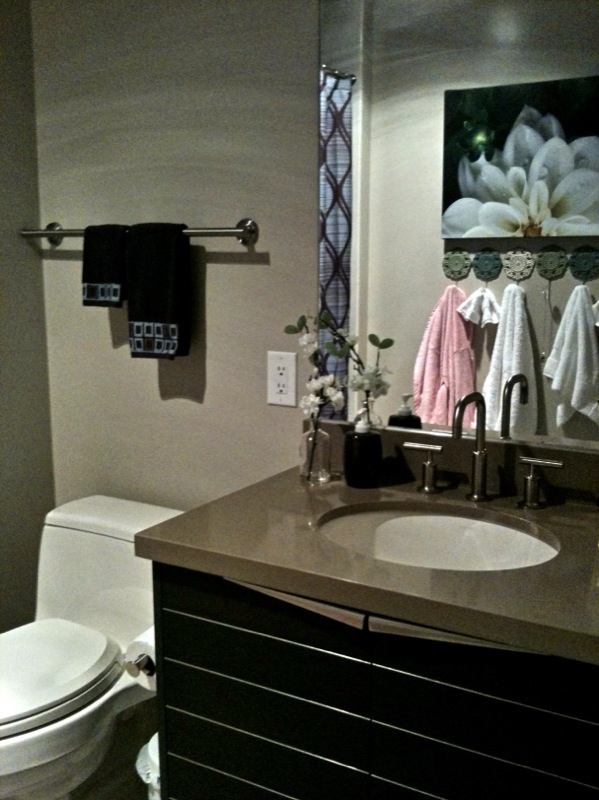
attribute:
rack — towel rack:
[14, 211, 274, 276]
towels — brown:
[14, 211, 274, 334]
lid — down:
[19, 618, 130, 724]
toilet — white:
[19, 494, 208, 724]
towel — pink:
[423, 284, 494, 415]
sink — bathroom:
[423, 284, 559, 598]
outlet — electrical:
[251, 345, 325, 424]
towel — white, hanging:
[552, 280, 593, 395]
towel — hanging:
[469, 283, 555, 423]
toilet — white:
[32, 496, 257, 694]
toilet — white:
[25, 516, 217, 737]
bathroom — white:
[35, 115, 593, 686]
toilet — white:
[14, 571, 168, 742]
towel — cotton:
[86, 227, 246, 378]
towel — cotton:
[119, 217, 201, 367]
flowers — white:
[291, 325, 348, 420]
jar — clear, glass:
[294, 410, 336, 487]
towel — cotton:
[550, 282, 594, 407]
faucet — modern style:
[444, 384, 490, 502]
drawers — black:
[151, 556, 375, 665]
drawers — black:
[366, 601, 597, 720]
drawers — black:
[161, 604, 374, 722]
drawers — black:
[370, 658, 598, 795]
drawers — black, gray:
[155, 656, 371, 774]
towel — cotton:
[477, 286, 538, 368]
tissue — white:
[127, 624, 156, 689]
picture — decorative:
[441, 70, 597, 254]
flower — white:
[442, 105, 597, 235]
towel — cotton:
[78, 224, 119, 292]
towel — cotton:
[400, 283, 479, 426]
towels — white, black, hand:
[394, 208, 489, 457]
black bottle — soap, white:
[345, 427, 381, 488]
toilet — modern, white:
[4, 492, 161, 796]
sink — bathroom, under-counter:
[317, 502, 563, 572]